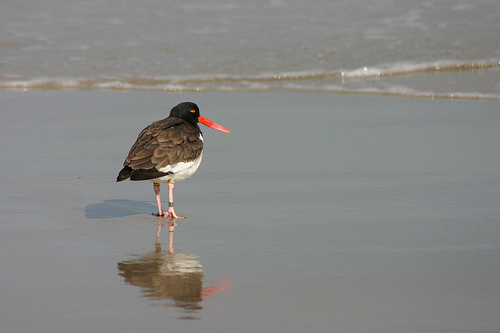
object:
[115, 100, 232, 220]
bird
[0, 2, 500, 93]
water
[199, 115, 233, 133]
beak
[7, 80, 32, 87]
part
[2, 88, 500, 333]
beach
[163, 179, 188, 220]
leg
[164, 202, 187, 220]
foot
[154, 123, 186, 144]
feather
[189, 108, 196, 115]
eye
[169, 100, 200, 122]
head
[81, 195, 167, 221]
shadow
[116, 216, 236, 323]
reflection